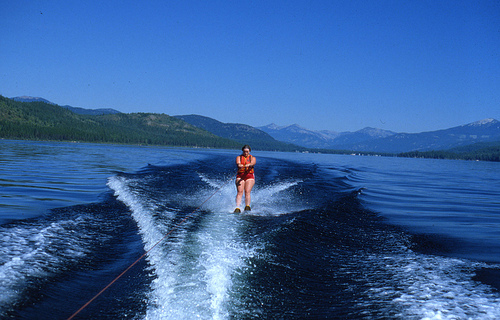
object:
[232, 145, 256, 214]
woman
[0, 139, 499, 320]
water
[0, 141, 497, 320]
blue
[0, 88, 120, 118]
hill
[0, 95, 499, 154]
mountains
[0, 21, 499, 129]
sky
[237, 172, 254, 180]
red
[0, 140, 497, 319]
lake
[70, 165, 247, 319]
rope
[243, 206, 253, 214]
skiis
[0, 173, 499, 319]
waves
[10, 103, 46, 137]
green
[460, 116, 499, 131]
snow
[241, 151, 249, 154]
sunglasses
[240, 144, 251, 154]
hair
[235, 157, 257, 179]
orange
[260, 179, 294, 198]
white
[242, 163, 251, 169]
hands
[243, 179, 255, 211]
legs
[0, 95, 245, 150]
tree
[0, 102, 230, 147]
hilside